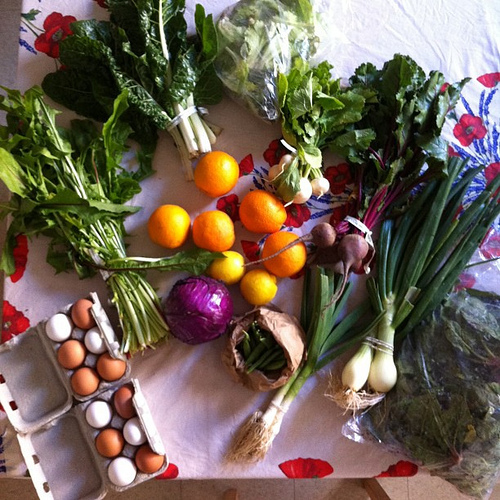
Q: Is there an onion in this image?
A: Yes, there are onions.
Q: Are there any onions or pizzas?
A: Yes, there are onions.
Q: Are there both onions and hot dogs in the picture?
A: No, there are onions but no hot dogs.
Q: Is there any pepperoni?
A: No, there is no pepperoni.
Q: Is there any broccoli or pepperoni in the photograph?
A: No, there are no pepperoni or broccoli.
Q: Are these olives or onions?
A: These are onions.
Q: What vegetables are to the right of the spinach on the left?
A: The vegetables are onions.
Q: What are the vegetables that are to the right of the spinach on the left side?
A: The vegetables are onions.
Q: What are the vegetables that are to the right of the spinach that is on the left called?
A: The vegetables are onions.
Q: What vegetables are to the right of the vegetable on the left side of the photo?
A: The vegetables are onions.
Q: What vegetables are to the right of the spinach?
A: The vegetables are onions.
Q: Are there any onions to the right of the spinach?
A: Yes, there are onions to the right of the spinach.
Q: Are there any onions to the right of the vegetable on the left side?
A: Yes, there are onions to the right of the spinach.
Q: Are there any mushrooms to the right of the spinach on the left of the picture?
A: No, there are onions to the right of the spinach.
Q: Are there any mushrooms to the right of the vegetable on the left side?
A: No, there are onions to the right of the spinach.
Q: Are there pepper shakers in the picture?
A: No, there are no pepper shakers.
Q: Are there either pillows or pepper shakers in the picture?
A: No, there are no pepper shakers or pillows.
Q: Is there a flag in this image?
A: No, there are no flags.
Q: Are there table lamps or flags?
A: No, there are no flags or table lamps.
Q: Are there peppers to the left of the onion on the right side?
A: No, there are fruits to the left of the onion.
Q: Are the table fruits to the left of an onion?
A: Yes, the fruits are to the left of an onion.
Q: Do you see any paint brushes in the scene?
A: No, there are no paint brushes.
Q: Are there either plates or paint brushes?
A: No, there are no paint brushes or plates.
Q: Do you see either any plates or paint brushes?
A: No, there are no paint brushes or plates.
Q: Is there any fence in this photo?
A: No, there are no fences.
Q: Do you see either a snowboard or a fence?
A: No, there are no fences or snowboards.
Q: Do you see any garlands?
A: No, there are no garlands.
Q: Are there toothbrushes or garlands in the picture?
A: No, there are no garlands or toothbrushes.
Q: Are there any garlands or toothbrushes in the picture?
A: No, there are no garlands or toothbrushes.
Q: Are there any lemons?
A: Yes, there is a lemon.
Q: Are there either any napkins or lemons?
A: Yes, there is a lemon.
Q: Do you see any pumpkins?
A: No, there are no pumpkins.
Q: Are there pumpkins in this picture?
A: No, there are no pumpkins.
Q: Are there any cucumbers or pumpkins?
A: No, there are no pumpkins or cucumbers.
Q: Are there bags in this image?
A: Yes, there is a bag.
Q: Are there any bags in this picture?
A: Yes, there is a bag.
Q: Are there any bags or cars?
A: Yes, there is a bag.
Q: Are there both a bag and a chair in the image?
A: No, there is a bag but no chairs.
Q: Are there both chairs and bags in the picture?
A: No, there is a bag but no chairs.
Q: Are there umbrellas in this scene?
A: No, there are no umbrellas.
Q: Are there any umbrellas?
A: No, there are no umbrellas.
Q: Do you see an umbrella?
A: No, there are no umbrellas.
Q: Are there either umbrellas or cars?
A: No, there are no umbrellas or cars.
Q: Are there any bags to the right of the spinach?
A: Yes, there is a bag to the right of the spinach.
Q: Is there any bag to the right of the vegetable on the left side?
A: Yes, there is a bag to the right of the spinach.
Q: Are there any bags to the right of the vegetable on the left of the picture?
A: Yes, there is a bag to the right of the spinach.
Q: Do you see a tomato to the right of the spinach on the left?
A: No, there is a bag to the right of the spinach.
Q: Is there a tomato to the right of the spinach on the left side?
A: No, there is a bag to the right of the spinach.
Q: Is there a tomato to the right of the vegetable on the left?
A: No, there is a bag to the right of the spinach.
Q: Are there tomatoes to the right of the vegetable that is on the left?
A: No, there is a bag to the right of the spinach.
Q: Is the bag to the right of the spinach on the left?
A: Yes, the bag is to the right of the spinach.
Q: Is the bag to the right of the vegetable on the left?
A: Yes, the bag is to the right of the spinach.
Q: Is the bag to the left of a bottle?
A: No, the bag is to the left of the onion.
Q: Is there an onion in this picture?
A: Yes, there is an onion.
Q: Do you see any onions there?
A: Yes, there is an onion.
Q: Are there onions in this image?
A: Yes, there is an onion.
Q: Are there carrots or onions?
A: Yes, there is an onion.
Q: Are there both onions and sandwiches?
A: No, there is an onion but no sandwiches.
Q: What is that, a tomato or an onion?
A: That is an onion.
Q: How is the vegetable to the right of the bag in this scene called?
A: The vegetable is an onion.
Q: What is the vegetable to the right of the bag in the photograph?
A: The vegetable is an onion.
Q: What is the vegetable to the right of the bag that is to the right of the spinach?
A: The vegetable is an onion.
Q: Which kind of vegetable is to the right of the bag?
A: The vegetable is an onion.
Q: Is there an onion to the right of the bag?
A: Yes, there is an onion to the right of the bag.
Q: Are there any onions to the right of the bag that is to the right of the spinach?
A: Yes, there is an onion to the right of the bag.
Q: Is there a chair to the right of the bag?
A: No, there is an onion to the right of the bag.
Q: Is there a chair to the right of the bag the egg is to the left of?
A: No, there is an onion to the right of the bag.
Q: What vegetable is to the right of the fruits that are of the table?
A: The vegetable is an onion.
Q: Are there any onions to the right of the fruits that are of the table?
A: Yes, there is an onion to the right of the fruits.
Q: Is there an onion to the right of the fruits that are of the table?
A: Yes, there is an onion to the right of the fruits.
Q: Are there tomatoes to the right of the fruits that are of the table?
A: No, there is an onion to the right of the fruits.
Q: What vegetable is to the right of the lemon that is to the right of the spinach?
A: The vegetable is an onion.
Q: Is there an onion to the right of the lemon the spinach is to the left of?
A: Yes, there is an onion to the right of the lemon.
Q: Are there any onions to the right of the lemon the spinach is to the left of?
A: Yes, there is an onion to the right of the lemon.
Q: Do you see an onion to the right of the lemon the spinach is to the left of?
A: Yes, there is an onion to the right of the lemon.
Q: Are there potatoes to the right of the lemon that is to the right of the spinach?
A: No, there is an onion to the right of the lemon.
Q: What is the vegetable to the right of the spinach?
A: The vegetable is an onion.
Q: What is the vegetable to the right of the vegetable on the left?
A: The vegetable is an onion.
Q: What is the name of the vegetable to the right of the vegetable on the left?
A: The vegetable is an onion.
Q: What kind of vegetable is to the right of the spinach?
A: The vegetable is an onion.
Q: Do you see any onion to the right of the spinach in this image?
A: Yes, there is an onion to the right of the spinach.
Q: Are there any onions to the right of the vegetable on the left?
A: Yes, there is an onion to the right of the spinach.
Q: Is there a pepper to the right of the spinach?
A: No, there is an onion to the right of the spinach.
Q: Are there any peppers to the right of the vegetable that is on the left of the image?
A: No, there is an onion to the right of the spinach.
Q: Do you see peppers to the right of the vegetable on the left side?
A: No, there is an onion to the right of the spinach.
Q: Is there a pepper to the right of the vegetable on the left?
A: No, there is an onion to the right of the spinach.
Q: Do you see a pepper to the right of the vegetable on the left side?
A: No, there is an onion to the right of the spinach.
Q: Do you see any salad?
A: No, there is no salad.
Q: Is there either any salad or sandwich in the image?
A: No, there are no salad or sandwiches.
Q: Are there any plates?
A: No, there are no plates.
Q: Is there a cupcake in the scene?
A: No, there are no cupcakes.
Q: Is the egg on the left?
A: Yes, the egg is on the left of the image.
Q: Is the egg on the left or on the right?
A: The egg is on the left of the image.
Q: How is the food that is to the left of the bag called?
A: The food is an egg.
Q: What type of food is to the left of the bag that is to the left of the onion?
A: The food is an egg.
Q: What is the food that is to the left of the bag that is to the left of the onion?
A: The food is an egg.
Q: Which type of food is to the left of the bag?
A: The food is an egg.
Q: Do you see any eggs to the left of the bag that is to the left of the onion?
A: Yes, there is an egg to the left of the bag.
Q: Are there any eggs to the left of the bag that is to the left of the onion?
A: Yes, there is an egg to the left of the bag.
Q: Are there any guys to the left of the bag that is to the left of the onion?
A: No, there is an egg to the left of the bag.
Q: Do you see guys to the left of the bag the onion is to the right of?
A: No, there is an egg to the left of the bag.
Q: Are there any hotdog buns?
A: No, there are no hotdog buns.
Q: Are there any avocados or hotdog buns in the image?
A: No, there are no hotdog buns or avocados.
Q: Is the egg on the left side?
A: Yes, the egg is on the left of the image.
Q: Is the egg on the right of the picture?
A: No, the egg is on the left of the image.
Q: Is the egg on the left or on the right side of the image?
A: The egg is on the left of the image.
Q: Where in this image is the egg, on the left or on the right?
A: The egg is on the left of the image.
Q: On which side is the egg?
A: The egg is on the left of the image.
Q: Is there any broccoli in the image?
A: No, there is no broccoli.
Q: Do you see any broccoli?
A: No, there is no broccoli.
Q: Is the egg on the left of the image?
A: Yes, the egg is on the left of the image.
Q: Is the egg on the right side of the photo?
A: No, the egg is on the left of the image.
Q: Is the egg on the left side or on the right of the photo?
A: The egg is on the left of the image.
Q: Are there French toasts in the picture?
A: No, there are no French toasts.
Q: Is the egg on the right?
A: No, the egg is on the left of the image.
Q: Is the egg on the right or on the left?
A: The egg is on the left of the image.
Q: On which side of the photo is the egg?
A: The egg is on the left of the image.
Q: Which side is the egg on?
A: The egg is on the left of the image.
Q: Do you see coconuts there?
A: No, there are no coconuts.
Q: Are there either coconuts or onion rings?
A: No, there are no coconuts or onion rings.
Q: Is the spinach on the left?
A: Yes, the spinach is on the left of the image.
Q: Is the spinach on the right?
A: No, the spinach is on the left of the image.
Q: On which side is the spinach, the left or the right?
A: The spinach is on the left of the image.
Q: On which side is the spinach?
A: The spinach is on the left of the image.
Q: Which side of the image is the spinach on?
A: The spinach is on the left of the image.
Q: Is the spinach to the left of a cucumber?
A: No, the spinach is to the left of the onion.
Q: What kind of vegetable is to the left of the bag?
A: The vegetable is spinach.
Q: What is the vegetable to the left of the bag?
A: The vegetable is spinach.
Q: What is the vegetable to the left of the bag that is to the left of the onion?
A: The vegetable is spinach.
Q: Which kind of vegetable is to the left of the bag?
A: The vegetable is spinach.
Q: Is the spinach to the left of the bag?
A: Yes, the spinach is to the left of the bag.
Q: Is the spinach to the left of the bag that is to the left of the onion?
A: Yes, the spinach is to the left of the bag.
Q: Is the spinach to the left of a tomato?
A: No, the spinach is to the left of the bag.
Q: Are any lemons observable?
A: Yes, there is a lemon.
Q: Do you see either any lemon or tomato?
A: Yes, there is a lemon.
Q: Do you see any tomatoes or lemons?
A: Yes, there is a lemon.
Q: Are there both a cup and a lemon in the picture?
A: No, there is a lemon but no cups.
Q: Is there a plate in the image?
A: No, there are no plates.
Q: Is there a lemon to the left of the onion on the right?
A: Yes, there is a lemon to the left of the onion.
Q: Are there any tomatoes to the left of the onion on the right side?
A: No, there is a lemon to the left of the onion.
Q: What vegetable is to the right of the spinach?
A: The vegetable is a lemon.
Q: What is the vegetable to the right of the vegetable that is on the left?
A: The vegetable is a lemon.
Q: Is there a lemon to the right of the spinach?
A: Yes, there is a lemon to the right of the spinach.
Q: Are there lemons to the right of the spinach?
A: Yes, there is a lemon to the right of the spinach.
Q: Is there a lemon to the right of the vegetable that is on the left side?
A: Yes, there is a lemon to the right of the spinach.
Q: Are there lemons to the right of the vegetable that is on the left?
A: Yes, there is a lemon to the right of the spinach.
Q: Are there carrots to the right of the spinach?
A: No, there is a lemon to the right of the spinach.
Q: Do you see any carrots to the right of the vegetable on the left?
A: No, there is a lemon to the right of the spinach.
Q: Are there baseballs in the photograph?
A: No, there are no baseballs.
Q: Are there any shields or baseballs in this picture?
A: No, there are no baseballs or shields.